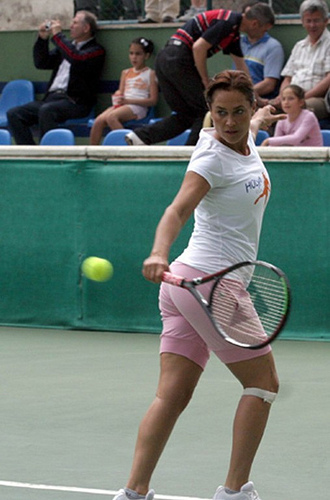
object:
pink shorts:
[157, 260, 272, 372]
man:
[124, 1, 275, 145]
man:
[268, 0, 330, 122]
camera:
[43, 21, 52, 32]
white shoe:
[207, 479, 267, 500]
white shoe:
[111, 487, 165, 500]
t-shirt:
[174, 125, 271, 290]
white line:
[0, 479, 205, 500]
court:
[0, 322, 330, 499]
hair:
[203, 69, 255, 113]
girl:
[260, 84, 324, 146]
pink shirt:
[268, 109, 323, 146]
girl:
[88, 35, 159, 146]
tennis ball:
[80, 255, 113, 284]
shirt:
[123, 66, 159, 100]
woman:
[110, 68, 287, 500]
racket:
[161, 259, 292, 350]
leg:
[170, 260, 283, 500]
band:
[241, 386, 277, 405]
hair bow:
[140, 38, 149, 48]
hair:
[129, 37, 155, 58]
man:
[5, 8, 106, 145]